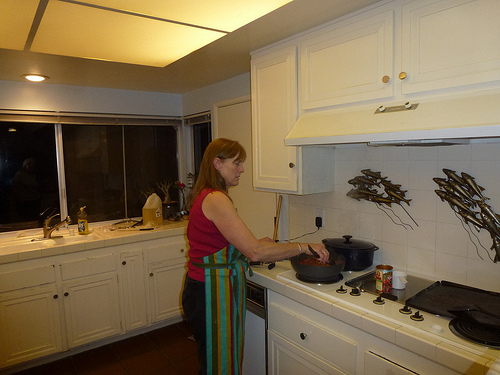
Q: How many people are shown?
A: 1.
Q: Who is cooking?
A: The woman.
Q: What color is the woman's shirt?
A: Red.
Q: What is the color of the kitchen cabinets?
A: White.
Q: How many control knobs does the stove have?
A: 5.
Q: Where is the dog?
A: There isn't one.